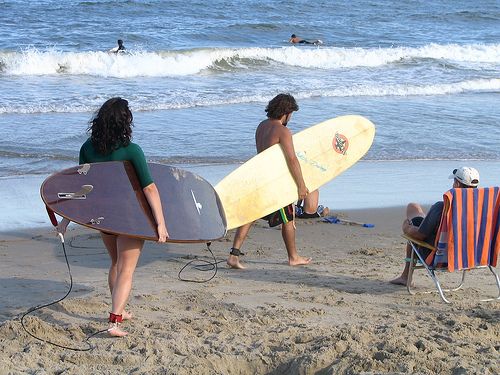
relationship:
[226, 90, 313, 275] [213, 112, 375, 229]
man holding surfboard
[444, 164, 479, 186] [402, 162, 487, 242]
baseball cap on person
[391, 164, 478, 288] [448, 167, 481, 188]
man wearing baseball cap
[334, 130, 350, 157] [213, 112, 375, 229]
symbol on surfboard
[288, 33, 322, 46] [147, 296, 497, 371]
man surfing at beach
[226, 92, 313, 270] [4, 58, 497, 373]
man are on beach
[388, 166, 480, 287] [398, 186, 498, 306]
man in beach chair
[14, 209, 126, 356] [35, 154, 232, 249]
bracelet attached to surfboard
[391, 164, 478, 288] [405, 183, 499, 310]
man sits in chair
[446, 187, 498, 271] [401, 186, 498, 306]
towel hangs over chair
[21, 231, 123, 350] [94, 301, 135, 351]
leash wrapped around ankle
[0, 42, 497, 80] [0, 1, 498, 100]
wave crashing on ocean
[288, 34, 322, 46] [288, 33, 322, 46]
man lying on man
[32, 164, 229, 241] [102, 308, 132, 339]
board attached to ankle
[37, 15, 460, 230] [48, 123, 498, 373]
water at beach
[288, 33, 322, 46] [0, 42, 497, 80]
man riding wave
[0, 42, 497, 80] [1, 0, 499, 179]
wave in water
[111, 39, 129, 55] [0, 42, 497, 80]
surfer riding wave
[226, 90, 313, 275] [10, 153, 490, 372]
man walking on beach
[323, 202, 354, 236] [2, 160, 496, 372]
shovel in sand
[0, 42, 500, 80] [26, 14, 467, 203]
wave in ocean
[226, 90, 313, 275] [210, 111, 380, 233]
man carry surf board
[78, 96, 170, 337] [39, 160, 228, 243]
surfers carry board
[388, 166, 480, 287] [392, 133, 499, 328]
man sitting in beach chair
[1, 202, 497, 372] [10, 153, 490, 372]
sand on beach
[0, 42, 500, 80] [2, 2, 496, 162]
wave in water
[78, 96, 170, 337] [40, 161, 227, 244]
surfers with surfboard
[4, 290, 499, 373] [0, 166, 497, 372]
footprints in sandy beach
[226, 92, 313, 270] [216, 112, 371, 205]
man holding surfboards